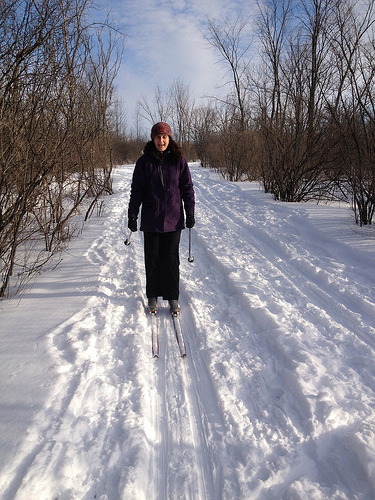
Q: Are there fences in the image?
A: No, there are no fences.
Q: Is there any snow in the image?
A: Yes, there is snow.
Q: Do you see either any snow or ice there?
A: Yes, there is snow.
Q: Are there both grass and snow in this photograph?
A: No, there is snow but no grass.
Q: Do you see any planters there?
A: No, there are no planters.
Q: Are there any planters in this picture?
A: No, there are no planters.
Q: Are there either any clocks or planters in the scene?
A: No, there are no planters or clocks.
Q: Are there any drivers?
A: No, there are no drivers.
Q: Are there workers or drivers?
A: No, there are no drivers or workers.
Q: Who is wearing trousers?
A: The skier is wearing trousers.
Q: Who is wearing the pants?
A: The skier is wearing trousers.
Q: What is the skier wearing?
A: The skier is wearing pants.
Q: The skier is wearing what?
A: The skier is wearing pants.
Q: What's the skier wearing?
A: The skier is wearing pants.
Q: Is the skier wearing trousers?
A: Yes, the skier is wearing trousers.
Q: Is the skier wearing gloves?
A: No, the skier is wearing trousers.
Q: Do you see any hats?
A: Yes, there is a hat.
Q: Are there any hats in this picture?
A: Yes, there is a hat.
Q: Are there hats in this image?
A: Yes, there is a hat.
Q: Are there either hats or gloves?
A: Yes, there is a hat.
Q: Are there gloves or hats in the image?
A: Yes, there is a hat.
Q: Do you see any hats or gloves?
A: Yes, there is a hat.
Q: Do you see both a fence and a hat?
A: No, there is a hat but no fences.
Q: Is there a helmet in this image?
A: No, there are no helmets.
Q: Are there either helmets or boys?
A: No, there are no helmets or boys.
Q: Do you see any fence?
A: No, there are no fences.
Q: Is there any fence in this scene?
A: No, there are no fences.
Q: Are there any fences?
A: No, there are no fences.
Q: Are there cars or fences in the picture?
A: No, there are no fences or cars.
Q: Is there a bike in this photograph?
A: No, there are no bikes.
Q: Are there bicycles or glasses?
A: No, there are no bicycles or glasses.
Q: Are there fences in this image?
A: No, there are no fences.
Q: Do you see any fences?
A: No, there are no fences.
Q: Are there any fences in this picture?
A: No, there are no fences.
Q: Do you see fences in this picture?
A: No, there are no fences.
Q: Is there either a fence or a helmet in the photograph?
A: No, there are no fences or helmets.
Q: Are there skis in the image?
A: Yes, there are skis.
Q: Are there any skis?
A: Yes, there are skis.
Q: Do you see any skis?
A: Yes, there are skis.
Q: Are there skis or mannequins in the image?
A: Yes, there are skis.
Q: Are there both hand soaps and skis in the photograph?
A: No, there are skis but no hand soaps.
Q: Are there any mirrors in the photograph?
A: No, there are no mirrors.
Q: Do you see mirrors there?
A: No, there are no mirrors.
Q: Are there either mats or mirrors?
A: No, there are no mirrors or mats.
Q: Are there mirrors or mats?
A: No, there are no mirrors or mats.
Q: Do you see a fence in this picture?
A: No, there are no fences.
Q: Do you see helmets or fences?
A: No, there are no fences or helmets.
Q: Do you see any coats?
A: Yes, there is a coat.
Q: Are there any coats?
A: Yes, there is a coat.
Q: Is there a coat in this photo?
A: Yes, there is a coat.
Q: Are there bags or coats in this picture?
A: Yes, there is a coat.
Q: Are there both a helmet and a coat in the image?
A: No, there is a coat but no helmets.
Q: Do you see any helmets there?
A: No, there are no helmets.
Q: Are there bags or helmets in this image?
A: No, there are no helmets or bags.